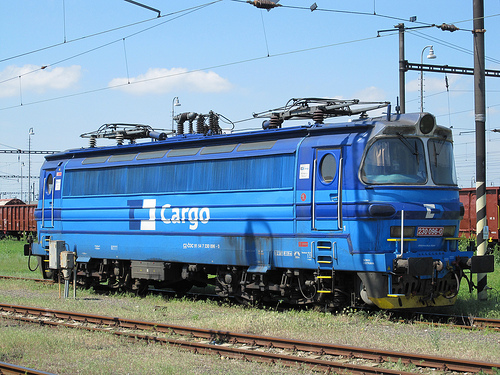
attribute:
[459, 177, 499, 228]
train — red , industrial 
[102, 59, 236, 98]
cloud — puffy, white 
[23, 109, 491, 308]
train car — blue, painted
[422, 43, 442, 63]
lamp — tall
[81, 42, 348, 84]
sky — clear , blue 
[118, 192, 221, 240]
logo — blue, white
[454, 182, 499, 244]
car — red, large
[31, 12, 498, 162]
wires — overhanging 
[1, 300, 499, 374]
tracks — brown , metal 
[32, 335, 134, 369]
grassy landscape — grassy 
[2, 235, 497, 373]
grass — long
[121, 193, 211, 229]
logo — blue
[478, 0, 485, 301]
poles — utility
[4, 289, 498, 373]
tracks — rusty 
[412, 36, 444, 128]
light pole — metal 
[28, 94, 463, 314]
train — blue   